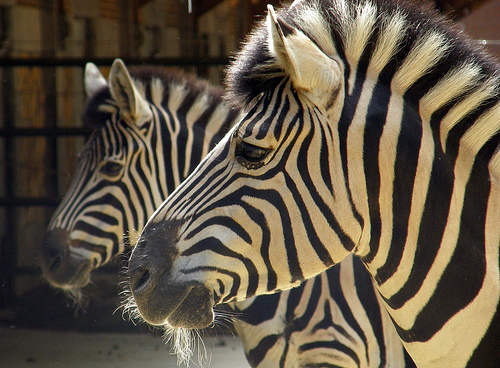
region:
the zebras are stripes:
[56, 37, 484, 347]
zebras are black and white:
[62, 57, 457, 365]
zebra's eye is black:
[222, 125, 294, 183]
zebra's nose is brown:
[114, 187, 234, 320]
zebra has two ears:
[53, 54, 180, 144]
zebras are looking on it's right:
[8, 47, 426, 365]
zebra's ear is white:
[89, 65, 204, 162]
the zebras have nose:
[13, 191, 318, 366]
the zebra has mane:
[368, 16, 498, 126]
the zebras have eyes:
[49, 125, 349, 231]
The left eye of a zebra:
[230, 128, 277, 164]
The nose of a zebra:
[120, 259, 159, 301]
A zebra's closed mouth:
[160, 284, 216, 334]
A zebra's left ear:
[256, 4, 346, 117]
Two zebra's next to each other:
[22, 6, 387, 338]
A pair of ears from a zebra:
[57, 58, 158, 137]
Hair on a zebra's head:
[220, 0, 493, 117]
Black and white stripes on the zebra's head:
[156, 141, 236, 233]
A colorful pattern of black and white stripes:
[188, 171, 359, 291]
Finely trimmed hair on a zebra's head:
[386, 0, 496, 81]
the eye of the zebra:
[232, 138, 277, 166]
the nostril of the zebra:
[127, 262, 154, 294]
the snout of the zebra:
[124, 217, 222, 333]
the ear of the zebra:
[263, 1, 341, 106]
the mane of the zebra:
[218, 0, 498, 186]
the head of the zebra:
[116, 0, 377, 362]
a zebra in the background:
[35, 51, 423, 366]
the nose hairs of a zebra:
[110, 226, 149, 330]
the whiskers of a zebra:
[164, 305, 246, 367]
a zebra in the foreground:
[113, 0, 498, 366]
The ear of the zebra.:
[256, 4, 341, 95]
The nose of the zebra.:
[124, 222, 167, 294]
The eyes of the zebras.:
[103, 133, 299, 178]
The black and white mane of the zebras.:
[143, 18, 498, 124]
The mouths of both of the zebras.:
[25, 225, 212, 342]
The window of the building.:
[11, 7, 49, 334]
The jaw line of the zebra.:
[266, 187, 364, 291]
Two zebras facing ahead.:
[35, 20, 496, 366]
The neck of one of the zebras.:
[373, 235, 498, 367]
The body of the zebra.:
[238, 325, 397, 367]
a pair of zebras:
[36, 3, 484, 346]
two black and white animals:
[36, 11, 489, 356]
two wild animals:
[45, 40, 485, 352]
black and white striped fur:
[368, 105, 473, 297]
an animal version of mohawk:
[111, 52, 229, 138]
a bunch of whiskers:
[111, 230, 241, 357]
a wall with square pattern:
[3, 62, 112, 264]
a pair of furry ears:
[67, 54, 154, 123]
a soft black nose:
[110, 195, 245, 336]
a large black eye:
[92, 151, 136, 183]